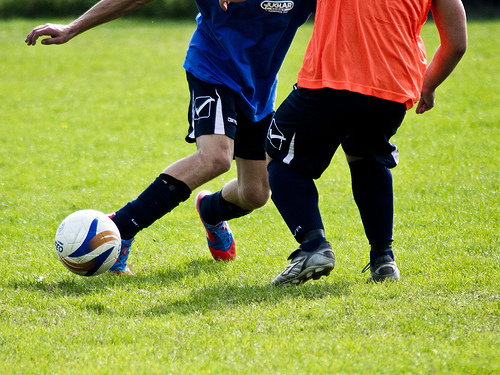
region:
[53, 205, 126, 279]
Multi-colored soccer ball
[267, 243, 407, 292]
Pair of soccer boots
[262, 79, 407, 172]
Pair of black sports shorts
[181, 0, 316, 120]
Blue colored sports shirt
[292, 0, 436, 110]
Orange colored sports shirt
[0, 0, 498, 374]
Field of short green grass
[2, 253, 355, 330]
Shadows on the grand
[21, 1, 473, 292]
Two players tussling for the ball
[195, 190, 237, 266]
Red colored soccer boot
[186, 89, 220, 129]
Branding on the pair of shorts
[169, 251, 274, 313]
shadow cast on the grass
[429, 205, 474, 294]
bright grass on the field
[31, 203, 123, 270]
round white soccer ball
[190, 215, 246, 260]
red and blue soccer shoes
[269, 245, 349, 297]
white and gray shoes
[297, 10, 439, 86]
large orange tee shirt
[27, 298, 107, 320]
white flecks on the grass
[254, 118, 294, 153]
white check on black shorts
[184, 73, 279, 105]
edge of blue shirt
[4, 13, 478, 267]
players kicking soccer ball on field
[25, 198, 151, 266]
white soccer ball on field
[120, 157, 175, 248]
tall black sock on player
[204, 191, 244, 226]
tall black sock on player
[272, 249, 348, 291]
gray cleats on player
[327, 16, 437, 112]
orange shirt on soccer player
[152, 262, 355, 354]
short green grass under players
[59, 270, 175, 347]
shadows of men on field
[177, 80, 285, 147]
black shorts on player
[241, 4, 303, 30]
white logo on blue shirt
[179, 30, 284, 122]
blue shirt on player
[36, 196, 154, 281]
a white blue and gold ball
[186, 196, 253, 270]
blue and red shoes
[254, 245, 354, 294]
gray and black shoes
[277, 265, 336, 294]
white cleets on bottom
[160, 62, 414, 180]
black and white shorts on both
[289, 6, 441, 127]
an orange shirt on one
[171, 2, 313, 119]
a blue shirt with white letters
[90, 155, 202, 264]
black socks on legs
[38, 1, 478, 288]
two guys playing soccer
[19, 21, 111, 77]
a hand in the air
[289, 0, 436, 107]
an orange shirt on a person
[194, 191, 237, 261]
a red and blue soccer cleat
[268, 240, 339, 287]
a black and grey soccer cleat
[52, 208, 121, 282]
a white soccer ball with blue and gold markings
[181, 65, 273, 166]
black and white shorts on a man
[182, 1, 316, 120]
a blue shirt on a man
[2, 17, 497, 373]
a grassy soccer field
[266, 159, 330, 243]
a navy sock covering a shin guard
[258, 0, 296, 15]
white print on a blue shirt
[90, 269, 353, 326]
the shadow of a soccer player on the ground